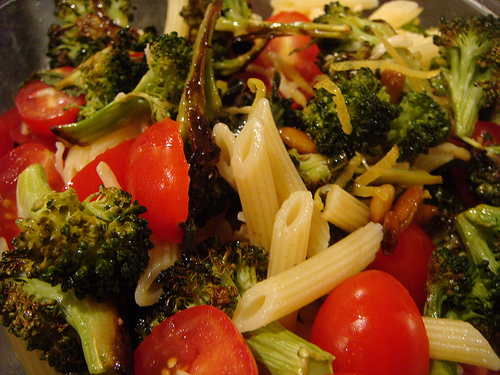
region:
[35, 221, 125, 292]
FRESH GREEN BROCCOLI FLOWERETTS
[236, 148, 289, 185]
COOKED RIGGATONI PASTA SHELLS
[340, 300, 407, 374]
FRESH RED CHERRY TOMATO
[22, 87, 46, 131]
CUT RED CHERRY TOMATO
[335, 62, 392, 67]
SLICE OF SHREDDED CHEESE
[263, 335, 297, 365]
STALK OF FRESH BROCCOLI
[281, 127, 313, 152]
A SINGLE COOKED RED BEAN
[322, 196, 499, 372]
PASTA SALAD WITH TOMATO, BEANS, AND BROCOLLI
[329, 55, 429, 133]
SALAD WITH CHEESE, BROCCOLI, AND BEAN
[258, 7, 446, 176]
PASTA SALAD, WITH TOMATO, CHEESE, BROCCOLI, BEAN, DRESSING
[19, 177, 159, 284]
cooked green broccoli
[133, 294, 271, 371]
half red tomato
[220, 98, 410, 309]
cooked pasta with vegtables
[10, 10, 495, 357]
variety of vegetable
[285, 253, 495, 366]
red tomato in half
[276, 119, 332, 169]
one beans under vegtables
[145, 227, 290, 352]
well done broccoli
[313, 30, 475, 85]
shredded cheese on vegetable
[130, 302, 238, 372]
red tomato with seeds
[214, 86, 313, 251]
cooked four pieces pasta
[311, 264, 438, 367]
the tomato is red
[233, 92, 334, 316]
the pasta is yellow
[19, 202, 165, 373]
the veggie is green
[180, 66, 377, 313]
the food is oily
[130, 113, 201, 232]
the tomato is sliced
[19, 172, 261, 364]
the food is veggies and pasta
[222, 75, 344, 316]
the pasta is penne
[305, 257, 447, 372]
the tomato is cherry tomato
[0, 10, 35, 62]
the background is gray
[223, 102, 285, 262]
the pasta has lines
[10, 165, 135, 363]
broccoli is green and yummy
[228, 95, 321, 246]
pasta is yellow and savory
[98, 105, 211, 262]
tomato is red and juicy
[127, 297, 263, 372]
tomato has yellow seeds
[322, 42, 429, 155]
broccoli is black on top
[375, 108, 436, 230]
cheese is visible in salad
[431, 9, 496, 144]
broccoli is lush and green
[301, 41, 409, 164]
cheese on top of broccoli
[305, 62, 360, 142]
cheese is slightly melted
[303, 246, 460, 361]
tomato is round and red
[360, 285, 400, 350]
this is a tomato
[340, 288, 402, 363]
the tomato is red in color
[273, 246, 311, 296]
this is some macoroni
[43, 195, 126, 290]
this is brocolli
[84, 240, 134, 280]
the brocolli is green in color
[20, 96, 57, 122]
the tomato is sliced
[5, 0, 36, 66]
this is a table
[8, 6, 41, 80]
the table is made of marble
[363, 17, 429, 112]
these are some spices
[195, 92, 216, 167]
this is red spice